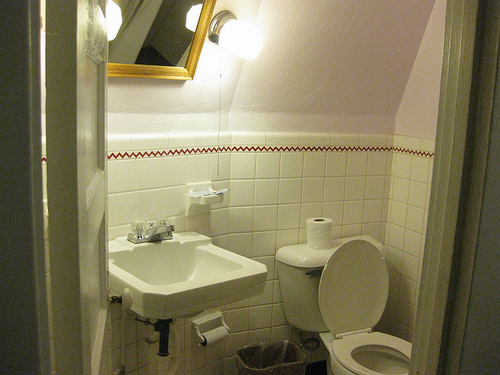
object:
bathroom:
[40, 1, 476, 375]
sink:
[107, 230, 268, 320]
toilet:
[318, 330, 414, 374]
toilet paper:
[305, 217, 333, 251]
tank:
[274, 233, 385, 332]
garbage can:
[234, 340, 307, 375]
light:
[208, 9, 265, 61]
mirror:
[105, 0, 207, 70]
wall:
[39, 0, 452, 375]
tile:
[255, 152, 282, 180]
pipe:
[157, 316, 174, 357]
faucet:
[126, 217, 175, 245]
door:
[44, 0, 116, 375]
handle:
[304, 269, 322, 278]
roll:
[200, 325, 229, 347]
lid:
[316, 239, 390, 339]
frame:
[104, 0, 217, 82]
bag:
[234, 340, 310, 375]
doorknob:
[108, 288, 135, 314]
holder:
[190, 311, 230, 344]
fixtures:
[130, 220, 147, 230]